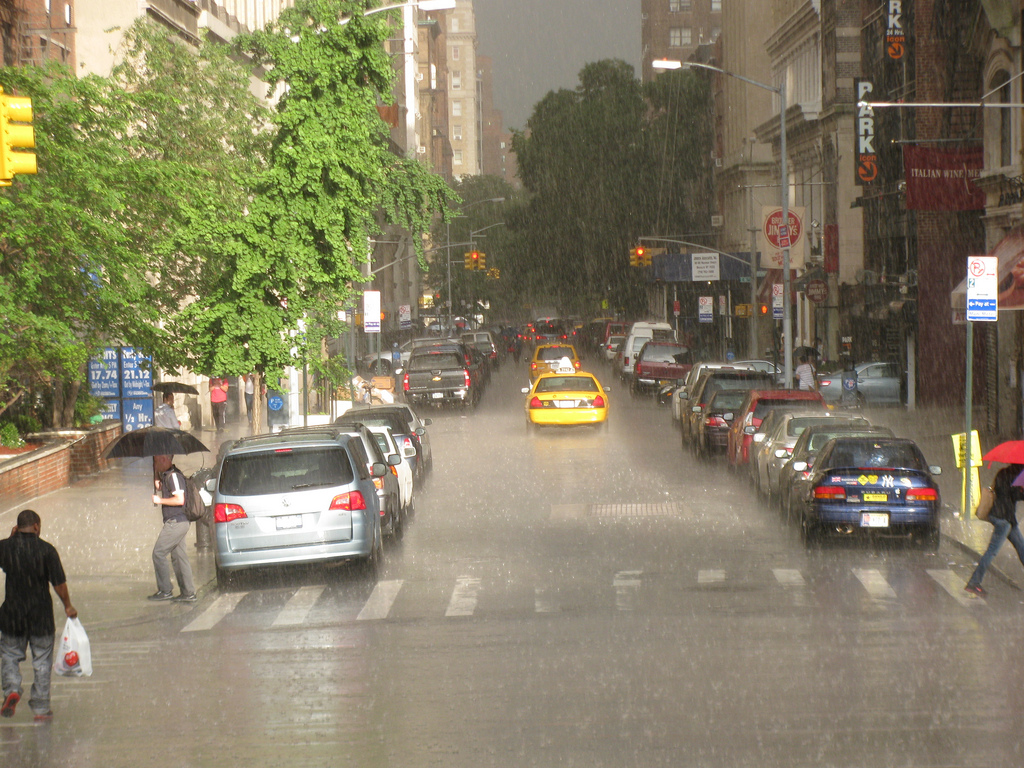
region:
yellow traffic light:
[0, 82, 39, 188]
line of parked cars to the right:
[596, 318, 944, 544]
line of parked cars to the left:
[202, 322, 498, 582]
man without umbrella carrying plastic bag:
[0, 508, 93, 717]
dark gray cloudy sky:
[480, 0, 639, 133]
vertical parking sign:
[850, 79, 883, 185]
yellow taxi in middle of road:
[520, 357, 613, 437]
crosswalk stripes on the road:
[180, 562, 991, 629]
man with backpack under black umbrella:
[104, 420, 207, 611]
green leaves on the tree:
[222, 213, 296, 286]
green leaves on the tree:
[317, 121, 372, 175]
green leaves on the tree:
[143, 178, 207, 268]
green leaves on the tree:
[154, 11, 178, 98]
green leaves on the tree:
[350, 49, 388, 123]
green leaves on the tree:
[565, 58, 619, 160]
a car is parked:
[226, 428, 385, 577]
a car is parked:
[371, 415, 411, 501]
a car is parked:
[804, 442, 929, 551]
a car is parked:
[696, 372, 750, 446]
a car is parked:
[634, 340, 686, 395]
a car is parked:
[411, 353, 476, 410]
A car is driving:
[532, 366, 597, 424]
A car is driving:
[533, 346, 579, 373]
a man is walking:
[5, 504, 92, 720]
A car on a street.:
[209, 434, 388, 574]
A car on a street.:
[787, 422, 898, 514]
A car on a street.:
[748, 411, 873, 485]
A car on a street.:
[522, 368, 611, 426]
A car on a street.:
[524, 346, 573, 373]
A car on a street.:
[401, 342, 481, 397]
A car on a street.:
[634, 334, 695, 388]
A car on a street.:
[620, 318, 678, 379]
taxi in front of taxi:
[532, 339, 578, 385]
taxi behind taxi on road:
[517, 350, 614, 437]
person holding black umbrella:
[101, 427, 208, 606]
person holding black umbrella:
[148, 378, 200, 502]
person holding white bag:
[0, 508, 91, 718]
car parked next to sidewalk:
[191, 434, 389, 590]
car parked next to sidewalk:
[786, 430, 940, 550]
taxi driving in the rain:
[513, 364, 611, 435]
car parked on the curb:
[782, 435, 944, 556]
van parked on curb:
[193, 426, 389, 591]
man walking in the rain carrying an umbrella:
[133, 449, 195, 614]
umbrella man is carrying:
[99, 424, 207, 467]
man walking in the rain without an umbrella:
[1, 508, 81, 733]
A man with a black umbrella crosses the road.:
[94, 410, 230, 619]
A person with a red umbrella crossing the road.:
[954, 426, 1022, 607]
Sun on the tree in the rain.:
[68, 121, 439, 412]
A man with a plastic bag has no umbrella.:
[9, 500, 99, 723]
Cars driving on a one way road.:
[511, 290, 619, 449]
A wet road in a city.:
[228, 294, 1006, 759]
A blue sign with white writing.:
[73, 256, 160, 456]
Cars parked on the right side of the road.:
[593, 320, 948, 577]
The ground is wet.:
[413, 462, 856, 748]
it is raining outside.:
[104, 79, 961, 700]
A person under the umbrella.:
[89, 418, 230, 597]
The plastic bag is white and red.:
[49, 609, 103, 687]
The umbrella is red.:
[964, 420, 1021, 485]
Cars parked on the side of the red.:
[697, 354, 936, 583]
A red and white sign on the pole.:
[748, 202, 824, 272]